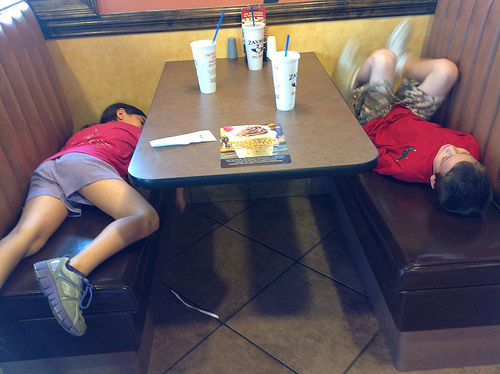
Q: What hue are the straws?
A: Blue.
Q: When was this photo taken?
A: Daytime.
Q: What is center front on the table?
A: Menu.